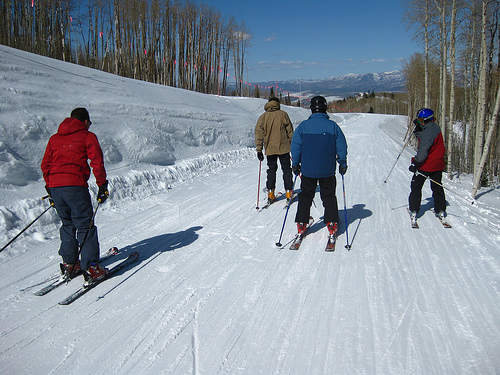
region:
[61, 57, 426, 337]
people are skiing in the filed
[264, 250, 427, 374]
floor is white in color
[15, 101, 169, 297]
a man is on skiingboards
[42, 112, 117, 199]
the jacket is red incolor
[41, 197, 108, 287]
pants are dark blue in color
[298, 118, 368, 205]
jacket is blue incolor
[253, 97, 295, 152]
the jacket is gray incolor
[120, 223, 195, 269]
shadow of the man is on the floor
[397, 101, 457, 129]
the helmet is blue in color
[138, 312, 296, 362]
the skiing stick opathway is on the floor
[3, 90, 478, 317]
a group of four people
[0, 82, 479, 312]
skiers on the snow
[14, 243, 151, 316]
a pair of skis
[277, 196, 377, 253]
shadow on the ground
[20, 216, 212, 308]
shadow from the skier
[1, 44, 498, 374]
white snow on the ground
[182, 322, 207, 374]
thin track in the snow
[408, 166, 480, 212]
ski pole sticking out behind the body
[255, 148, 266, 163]
black glove on the hand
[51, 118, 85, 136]
red hood on the jacket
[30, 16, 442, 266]
these are skiers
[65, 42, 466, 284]
these people are on a ski trail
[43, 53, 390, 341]
this is a ski course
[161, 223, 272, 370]
the ground has many tracks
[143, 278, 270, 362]
the ground is made of snow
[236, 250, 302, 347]
the snow is dirty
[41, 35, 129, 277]
the skier has a red jacket on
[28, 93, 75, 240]
the person is holding ski poles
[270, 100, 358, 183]
this person has a blue jacket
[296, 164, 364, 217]
this person has black pants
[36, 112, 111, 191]
the jacket is red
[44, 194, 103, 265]
the pants are blue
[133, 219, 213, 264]
shadow is on the ground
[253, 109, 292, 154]
the jacket is brown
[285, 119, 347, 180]
the jacket is blue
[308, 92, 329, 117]
the helmet is black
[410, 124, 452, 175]
the jacket is grey and red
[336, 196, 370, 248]
shadow is on the ground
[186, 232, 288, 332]
skitrail is on the ground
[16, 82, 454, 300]
the people are four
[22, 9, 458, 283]
skiers on the slopes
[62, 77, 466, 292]
four skiers on a trail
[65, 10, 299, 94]
red markers in the area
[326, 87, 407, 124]
trees in the distance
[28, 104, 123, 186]
he has on a red snow jacket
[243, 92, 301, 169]
his coat is brown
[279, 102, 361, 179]
his coat is blue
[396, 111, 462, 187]
his coat is red and sliver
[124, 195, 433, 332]
tracks are in the snow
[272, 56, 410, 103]
scenery of the are in the background